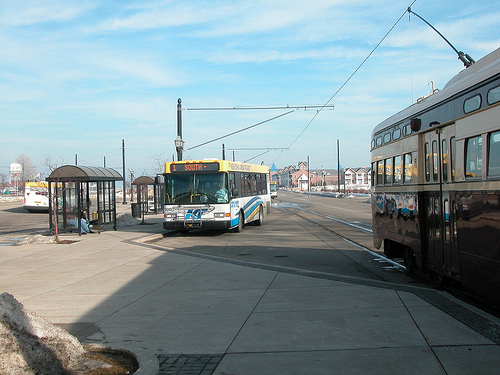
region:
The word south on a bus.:
[182, 161, 206, 172]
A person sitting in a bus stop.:
[69, 203, 95, 241]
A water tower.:
[5, 158, 27, 195]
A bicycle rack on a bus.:
[166, 200, 214, 232]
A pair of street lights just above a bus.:
[172, 133, 187, 153]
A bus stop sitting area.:
[45, 160, 130, 232]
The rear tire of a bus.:
[255, 202, 267, 226]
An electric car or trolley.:
[366, 47, 495, 272]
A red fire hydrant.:
[344, 189, 351, 199]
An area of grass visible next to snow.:
[85, 343, 147, 373]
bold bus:
[165, 154, 290, 232]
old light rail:
[353, 67, 497, 230]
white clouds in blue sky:
[10, 16, 73, 82]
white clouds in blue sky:
[17, 55, 37, 84]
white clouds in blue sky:
[15, 87, 43, 131]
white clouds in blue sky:
[56, 55, 96, 102]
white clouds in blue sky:
[91, 29, 155, 76]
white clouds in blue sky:
[192, 43, 231, 77]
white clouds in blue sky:
[223, 49, 277, 94]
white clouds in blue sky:
[281, 84, 328, 145]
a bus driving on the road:
[10, 42, 483, 339]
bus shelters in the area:
[36, 153, 163, 265]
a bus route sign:
[139, 154, 223, 179]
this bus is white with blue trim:
[168, 171, 288, 236]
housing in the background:
[276, 150, 361, 198]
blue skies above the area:
[29, 24, 355, 96]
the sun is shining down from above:
[30, 44, 367, 303]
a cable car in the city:
[334, 84, 499, 245]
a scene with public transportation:
[44, 59, 480, 331]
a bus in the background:
[9, 162, 58, 218]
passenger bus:
[160, 152, 274, 227]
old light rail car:
[348, 53, 480, 295]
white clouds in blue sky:
[23, 12, 69, 53]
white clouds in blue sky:
[67, 41, 117, 87]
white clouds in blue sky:
[48, 78, 94, 123]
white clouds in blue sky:
[81, 65, 131, 107]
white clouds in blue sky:
[188, 15, 238, 76]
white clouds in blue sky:
[286, 62, 345, 123]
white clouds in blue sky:
[230, 71, 259, 107]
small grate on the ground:
[153, 343, 233, 370]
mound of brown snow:
[2, 302, 82, 364]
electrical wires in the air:
[169, 78, 323, 144]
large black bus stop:
[43, 154, 130, 240]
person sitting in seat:
[71, 199, 102, 237]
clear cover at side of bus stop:
[51, 186, 86, 218]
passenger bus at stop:
[152, 151, 305, 222]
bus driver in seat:
[207, 179, 242, 207]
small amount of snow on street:
[320, 221, 375, 258]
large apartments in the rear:
[292, 163, 364, 190]